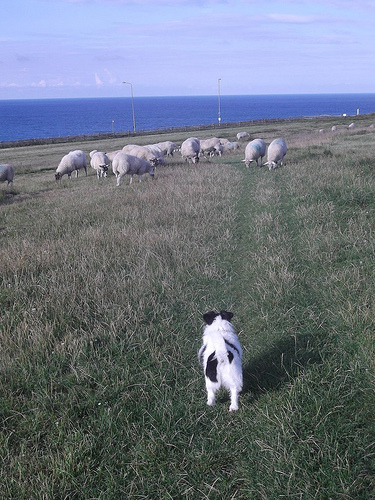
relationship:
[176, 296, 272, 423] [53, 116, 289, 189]
dog herding sheep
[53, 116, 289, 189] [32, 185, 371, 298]
sheep are in field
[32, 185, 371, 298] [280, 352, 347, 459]
field covered in grass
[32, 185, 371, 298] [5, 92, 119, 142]
field beside water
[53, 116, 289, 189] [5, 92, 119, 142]
sheep are beside water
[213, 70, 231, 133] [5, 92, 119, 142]
light beside water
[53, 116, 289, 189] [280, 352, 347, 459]
sheep are standing in grass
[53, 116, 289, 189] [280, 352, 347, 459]
sheep standing in grass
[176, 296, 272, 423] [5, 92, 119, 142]
dog beside water